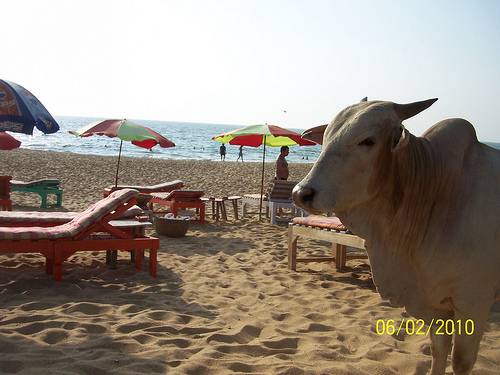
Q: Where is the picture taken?
A: Near a beach.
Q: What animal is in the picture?
A: A bull.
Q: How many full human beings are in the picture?
A: Three.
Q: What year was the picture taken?
A: 2010.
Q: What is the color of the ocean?
A: Blue.